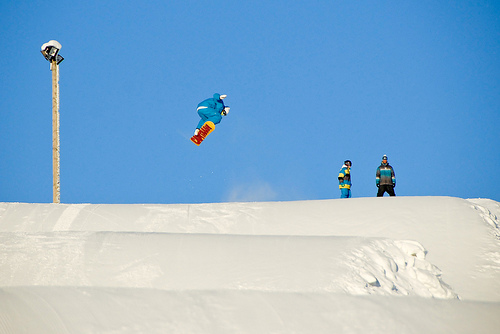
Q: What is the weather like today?
A: It is cloudless.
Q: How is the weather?
A: It is cloudless.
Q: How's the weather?
A: It is cloudless.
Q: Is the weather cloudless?
A: Yes, it is cloudless.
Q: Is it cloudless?
A: Yes, it is cloudless.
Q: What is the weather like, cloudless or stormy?
A: It is cloudless.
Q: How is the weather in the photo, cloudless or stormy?
A: It is cloudless.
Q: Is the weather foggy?
A: No, it is cloudless.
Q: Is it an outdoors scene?
A: Yes, it is outdoors.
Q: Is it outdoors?
A: Yes, it is outdoors.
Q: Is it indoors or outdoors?
A: It is outdoors.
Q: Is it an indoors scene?
A: No, it is outdoors.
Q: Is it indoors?
A: No, it is outdoors.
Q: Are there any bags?
A: No, there are no bags.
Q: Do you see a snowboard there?
A: Yes, there is a snowboard.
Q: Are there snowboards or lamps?
A: Yes, there is a snowboard.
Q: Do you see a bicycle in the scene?
A: No, there are no bicycles.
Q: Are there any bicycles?
A: No, there are no bicycles.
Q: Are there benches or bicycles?
A: No, there are no bicycles or benches.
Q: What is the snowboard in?
A: The snowboard is in the air.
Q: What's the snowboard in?
A: The snowboard is in the air.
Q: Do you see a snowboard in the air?
A: Yes, there is a snowboard in the air.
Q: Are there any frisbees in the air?
A: No, there is a snowboard in the air.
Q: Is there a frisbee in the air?
A: No, there is a snowboard in the air.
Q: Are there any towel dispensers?
A: No, there are no towel dispensers.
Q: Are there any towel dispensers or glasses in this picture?
A: No, there are no towel dispensers or glasses.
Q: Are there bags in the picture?
A: No, there are no bags.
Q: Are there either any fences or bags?
A: No, there are no bags or fences.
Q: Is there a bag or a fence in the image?
A: No, there are no bags or fences.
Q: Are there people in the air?
A: Yes, there is a person in the air.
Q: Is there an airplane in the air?
A: No, there is a person in the air.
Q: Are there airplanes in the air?
A: No, there is a person in the air.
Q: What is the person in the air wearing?
A: The person is wearing a jacket.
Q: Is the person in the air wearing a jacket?
A: Yes, the person is wearing a jacket.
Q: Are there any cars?
A: No, there are no cars.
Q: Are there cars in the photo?
A: No, there are no cars.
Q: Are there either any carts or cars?
A: No, there are no cars or carts.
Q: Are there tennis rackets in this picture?
A: No, there are no tennis rackets.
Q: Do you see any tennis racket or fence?
A: No, there are no rackets or fences.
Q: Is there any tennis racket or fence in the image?
A: No, there are no rackets or fences.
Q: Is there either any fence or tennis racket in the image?
A: No, there are no rackets or fences.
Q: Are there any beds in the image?
A: No, there are no beds.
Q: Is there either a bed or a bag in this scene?
A: No, there are no beds or bags.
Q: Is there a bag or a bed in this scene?
A: No, there are no beds or bags.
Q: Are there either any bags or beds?
A: No, there are no beds or bags.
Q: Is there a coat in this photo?
A: Yes, there is a coat.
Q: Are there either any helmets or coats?
A: Yes, there is a coat.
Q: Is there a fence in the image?
A: No, there are no fences.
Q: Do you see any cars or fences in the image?
A: No, there are no fences or cars.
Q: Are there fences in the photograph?
A: No, there are no fences.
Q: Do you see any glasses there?
A: No, there are no glasses.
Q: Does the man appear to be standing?
A: Yes, the man is standing.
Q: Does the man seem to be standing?
A: Yes, the man is standing.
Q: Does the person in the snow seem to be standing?
A: Yes, the man is standing.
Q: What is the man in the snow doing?
A: The man is standing.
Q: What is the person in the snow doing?
A: The man is standing.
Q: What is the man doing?
A: The man is standing.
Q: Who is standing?
A: The man is standing.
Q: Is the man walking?
A: No, the man is standing.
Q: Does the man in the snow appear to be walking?
A: No, the man is standing.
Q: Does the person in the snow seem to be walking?
A: No, the man is standing.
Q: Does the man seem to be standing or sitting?
A: The man is standing.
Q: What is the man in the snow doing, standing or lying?
A: The man is standing.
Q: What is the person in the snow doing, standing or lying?
A: The man is standing.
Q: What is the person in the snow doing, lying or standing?
A: The man is standing.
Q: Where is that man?
A: The man is in the snow.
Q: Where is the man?
A: The man is in the snow.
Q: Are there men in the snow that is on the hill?
A: Yes, there is a man in the snow.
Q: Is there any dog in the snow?
A: No, there is a man in the snow.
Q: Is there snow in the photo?
A: Yes, there is snow.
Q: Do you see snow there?
A: Yes, there is snow.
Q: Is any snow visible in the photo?
A: Yes, there is snow.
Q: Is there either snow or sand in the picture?
A: Yes, there is snow.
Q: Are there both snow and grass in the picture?
A: No, there is snow but no grass.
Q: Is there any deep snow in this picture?
A: Yes, there is deep snow.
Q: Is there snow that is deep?
A: Yes, there is snow that is deep.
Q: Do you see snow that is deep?
A: Yes, there is snow that is deep.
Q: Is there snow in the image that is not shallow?
A: Yes, there is deep snow.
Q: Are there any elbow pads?
A: No, there are no elbow pads.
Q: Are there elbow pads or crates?
A: No, there are no elbow pads or crates.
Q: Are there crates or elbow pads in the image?
A: No, there are no elbow pads or crates.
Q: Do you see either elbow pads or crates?
A: No, there are no elbow pads or crates.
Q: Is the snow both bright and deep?
A: Yes, the snow is bright and deep.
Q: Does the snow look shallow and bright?
A: No, the snow is bright but deep.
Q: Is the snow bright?
A: Yes, the snow is bright.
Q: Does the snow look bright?
A: Yes, the snow is bright.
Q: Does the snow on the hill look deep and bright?
A: Yes, the snow is deep and bright.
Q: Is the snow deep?
A: Yes, the snow is deep.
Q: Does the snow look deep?
A: Yes, the snow is deep.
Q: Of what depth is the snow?
A: The snow is deep.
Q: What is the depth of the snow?
A: The snow is deep.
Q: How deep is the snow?
A: The snow is deep.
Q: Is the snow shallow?
A: No, the snow is deep.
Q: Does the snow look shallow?
A: No, the snow is deep.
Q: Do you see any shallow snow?
A: No, there is snow but it is deep.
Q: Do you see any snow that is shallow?
A: No, there is snow but it is deep.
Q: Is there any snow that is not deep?
A: No, there is snow but it is deep.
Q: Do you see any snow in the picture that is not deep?
A: No, there is snow but it is deep.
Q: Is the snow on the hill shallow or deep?
A: The snow is deep.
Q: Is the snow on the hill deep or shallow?
A: The snow is deep.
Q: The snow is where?
A: The snow is on the hill.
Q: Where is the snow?
A: The snow is on the hill.